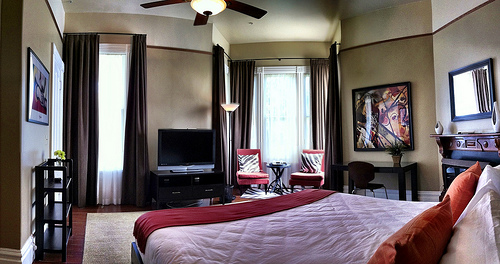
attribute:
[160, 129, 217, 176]
tv — large, flat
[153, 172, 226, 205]
table — black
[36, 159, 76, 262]
bookstand — black, small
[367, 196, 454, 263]
pillow — orange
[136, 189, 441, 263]
comforter — pink, red, white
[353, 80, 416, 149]
painting — framed, abstract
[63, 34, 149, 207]
curtain — open, brown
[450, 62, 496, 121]
mirror — large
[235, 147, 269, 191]
chair — red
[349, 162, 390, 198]
chair — black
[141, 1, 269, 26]
ceiling fan — hanging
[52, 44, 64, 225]
door — white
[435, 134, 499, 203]
fireplace mantel — black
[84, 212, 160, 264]
rug — white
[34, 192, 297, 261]
floor — hardwood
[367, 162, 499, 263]
pillows — orange, white